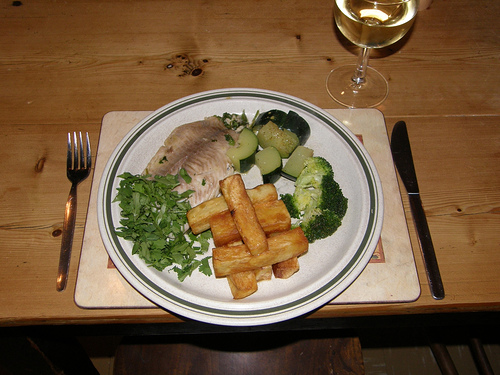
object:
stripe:
[184, 182, 308, 280]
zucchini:
[279, 142, 312, 181]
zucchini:
[254, 145, 284, 184]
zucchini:
[229, 126, 259, 173]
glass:
[324, 0, 420, 108]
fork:
[55, 125, 93, 292]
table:
[0, 0, 500, 328]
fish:
[142, 117, 242, 206]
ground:
[0, 327, 62, 375]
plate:
[93, 87, 381, 326]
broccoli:
[303, 177, 348, 218]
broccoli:
[293, 156, 335, 189]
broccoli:
[278, 191, 306, 219]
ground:
[475, 315, 500, 373]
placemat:
[73, 107, 422, 308]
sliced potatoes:
[212, 228, 307, 279]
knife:
[387, 121, 446, 300]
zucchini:
[255, 120, 302, 157]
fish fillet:
[168, 129, 236, 207]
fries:
[219, 174, 268, 257]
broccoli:
[301, 200, 344, 244]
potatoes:
[217, 174, 269, 256]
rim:
[104, 92, 376, 318]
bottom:
[325, 63, 389, 107]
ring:
[100, 89, 379, 319]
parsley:
[113, 169, 213, 280]